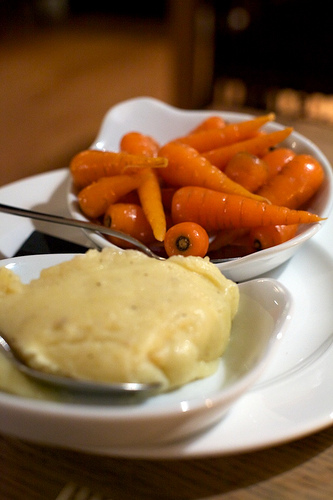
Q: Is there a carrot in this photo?
A: Yes, there are carrots.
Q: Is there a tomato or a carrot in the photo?
A: Yes, there are carrots.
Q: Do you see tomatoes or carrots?
A: Yes, there are carrots.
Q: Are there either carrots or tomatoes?
A: Yes, there are carrots.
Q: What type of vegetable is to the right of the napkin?
A: The vegetables are carrots.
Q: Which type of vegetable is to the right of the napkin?
A: The vegetables are carrots.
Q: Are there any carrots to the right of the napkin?
A: Yes, there are carrots to the right of the napkin.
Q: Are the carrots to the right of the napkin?
A: Yes, the carrots are to the right of the napkin.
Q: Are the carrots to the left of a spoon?
A: No, the carrots are to the right of a spoon.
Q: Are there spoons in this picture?
A: Yes, there is a spoon.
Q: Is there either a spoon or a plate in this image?
A: Yes, there is a spoon.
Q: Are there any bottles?
A: No, there are no bottles.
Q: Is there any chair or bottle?
A: No, there are no bottles or chairs.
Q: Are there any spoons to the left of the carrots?
A: Yes, there is a spoon to the left of the carrots.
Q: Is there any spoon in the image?
A: Yes, there is a spoon.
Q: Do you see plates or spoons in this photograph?
A: Yes, there is a spoon.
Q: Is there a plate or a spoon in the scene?
A: Yes, there is a spoon.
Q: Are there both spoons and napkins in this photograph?
A: Yes, there are both a spoon and a napkin.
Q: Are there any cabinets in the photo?
A: No, there are no cabinets.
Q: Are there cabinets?
A: No, there are no cabinets.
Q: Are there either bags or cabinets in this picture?
A: No, there are no cabinets or bags.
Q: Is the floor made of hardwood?
A: Yes, the floor is made of hardwood.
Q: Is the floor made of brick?
A: No, the floor is made of hardwood.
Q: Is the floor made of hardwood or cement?
A: The floor is made of hardwood.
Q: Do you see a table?
A: Yes, there is a table.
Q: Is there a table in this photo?
A: Yes, there is a table.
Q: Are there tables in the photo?
A: Yes, there is a table.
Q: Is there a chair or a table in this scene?
A: Yes, there is a table.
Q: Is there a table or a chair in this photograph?
A: Yes, there is a table.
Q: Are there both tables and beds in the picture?
A: No, there is a table but no beds.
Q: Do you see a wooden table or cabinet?
A: Yes, there is a wood table.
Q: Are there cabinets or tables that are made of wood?
A: Yes, the table is made of wood.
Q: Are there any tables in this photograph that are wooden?
A: Yes, there is a wood table.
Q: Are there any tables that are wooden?
A: Yes, there is a table that is wooden.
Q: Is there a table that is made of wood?
A: Yes, there is a table that is made of wood.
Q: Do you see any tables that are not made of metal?
A: Yes, there is a table that is made of wood.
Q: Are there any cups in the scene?
A: No, there are no cups.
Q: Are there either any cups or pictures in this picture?
A: No, there are no cups or pictures.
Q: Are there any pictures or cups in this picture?
A: No, there are no cups or pictures.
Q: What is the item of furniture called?
A: The piece of furniture is a table.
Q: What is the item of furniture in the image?
A: The piece of furniture is a table.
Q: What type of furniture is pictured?
A: The furniture is a table.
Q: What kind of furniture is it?
A: The piece of furniture is a table.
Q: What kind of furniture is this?
A: This is a table.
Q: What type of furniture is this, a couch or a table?
A: This is a table.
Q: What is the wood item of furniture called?
A: The piece of furniture is a table.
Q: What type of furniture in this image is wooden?
A: The furniture is a table.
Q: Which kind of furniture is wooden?
A: The furniture is a table.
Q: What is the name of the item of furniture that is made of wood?
A: The piece of furniture is a table.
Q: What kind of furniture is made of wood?
A: The furniture is a table.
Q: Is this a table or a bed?
A: This is a table.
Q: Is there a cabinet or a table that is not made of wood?
A: No, there is a table but it is made of wood.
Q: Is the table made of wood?
A: Yes, the table is made of wood.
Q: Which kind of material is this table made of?
A: The table is made of wood.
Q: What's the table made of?
A: The table is made of wood.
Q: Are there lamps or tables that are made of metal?
A: No, there is a table but it is made of wood.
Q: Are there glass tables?
A: No, there is a table but it is made of wood.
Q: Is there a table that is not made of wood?
A: No, there is a table but it is made of wood.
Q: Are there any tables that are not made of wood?
A: No, there is a table but it is made of wood.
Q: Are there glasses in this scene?
A: No, there are no glasses.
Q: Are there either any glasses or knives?
A: No, there are no glasses or knives.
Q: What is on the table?
A: The dish is on the table.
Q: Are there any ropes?
A: No, there are no ropes.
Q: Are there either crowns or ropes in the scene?
A: No, there are no ropes or crowns.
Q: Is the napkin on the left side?
A: Yes, the napkin is on the left of the image.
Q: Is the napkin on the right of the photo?
A: No, the napkin is on the left of the image.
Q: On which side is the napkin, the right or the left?
A: The napkin is on the left of the image.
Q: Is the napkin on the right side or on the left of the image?
A: The napkin is on the left of the image.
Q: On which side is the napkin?
A: The napkin is on the left of the image.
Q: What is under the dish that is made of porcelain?
A: The napkin is under the dish.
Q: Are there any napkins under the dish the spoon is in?
A: Yes, there is a napkin under the dish.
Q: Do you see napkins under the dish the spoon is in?
A: Yes, there is a napkin under the dish.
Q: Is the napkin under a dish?
A: Yes, the napkin is under a dish.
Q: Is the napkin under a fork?
A: No, the napkin is under a dish.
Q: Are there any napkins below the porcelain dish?
A: Yes, there is a napkin below the dish.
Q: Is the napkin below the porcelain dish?
A: Yes, the napkin is below the dish.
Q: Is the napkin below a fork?
A: No, the napkin is below the dish.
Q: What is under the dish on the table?
A: The napkin is under the dish.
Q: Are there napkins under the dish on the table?
A: Yes, there is a napkin under the dish.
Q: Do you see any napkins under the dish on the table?
A: Yes, there is a napkin under the dish.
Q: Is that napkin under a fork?
A: No, the napkin is under the dish.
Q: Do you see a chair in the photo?
A: No, there are no chairs.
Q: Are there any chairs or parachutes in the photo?
A: No, there are no chairs or parachutes.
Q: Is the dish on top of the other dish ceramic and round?
A: Yes, the dish is ceramic and round.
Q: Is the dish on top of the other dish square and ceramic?
A: No, the dish is ceramic but round.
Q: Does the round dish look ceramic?
A: Yes, the dish is ceramic.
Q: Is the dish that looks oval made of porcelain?
A: Yes, the dish is made of porcelain.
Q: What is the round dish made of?
A: The dish is made of porcelain.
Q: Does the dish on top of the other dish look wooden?
A: No, the dish is ceramic.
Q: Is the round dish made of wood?
A: No, the dish is made of porcelain.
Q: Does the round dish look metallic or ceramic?
A: The dish is ceramic.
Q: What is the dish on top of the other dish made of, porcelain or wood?
A: The dish is made of porcelain.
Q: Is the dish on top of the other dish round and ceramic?
A: Yes, the dish is round and ceramic.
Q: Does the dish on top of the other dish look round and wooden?
A: No, the dish is round but ceramic.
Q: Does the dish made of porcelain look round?
A: Yes, the dish is round.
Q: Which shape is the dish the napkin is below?
A: The dish is round.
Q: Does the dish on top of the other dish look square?
A: No, the dish is round.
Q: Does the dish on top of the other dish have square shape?
A: No, the dish is round.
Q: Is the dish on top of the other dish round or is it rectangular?
A: The dish is round.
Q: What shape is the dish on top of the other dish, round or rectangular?
A: The dish is round.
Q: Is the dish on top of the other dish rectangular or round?
A: The dish is round.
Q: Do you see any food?
A: Yes, there is food.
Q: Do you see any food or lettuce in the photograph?
A: Yes, there is food.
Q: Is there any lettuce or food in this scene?
A: Yes, there is food.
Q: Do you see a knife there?
A: No, there are no knives.